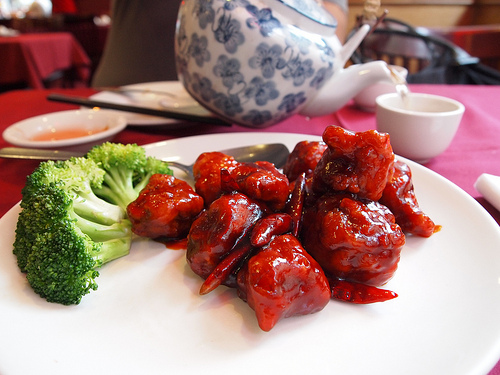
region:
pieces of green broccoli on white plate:
[6, 136, 183, 308]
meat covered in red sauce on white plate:
[116, 119, 447, 334]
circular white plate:
[1, 125, 498, 374]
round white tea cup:
[371, 80, 466, 170]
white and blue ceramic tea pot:
[170, 0, 415, 130]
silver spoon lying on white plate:
[0, 140, 292, 195]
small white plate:
[78, 69, 243, 140]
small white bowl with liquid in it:
[0, 105, 130, 162]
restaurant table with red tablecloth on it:
[0, 26, 95, 96]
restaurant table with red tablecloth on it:
[0, 76, 499, 374]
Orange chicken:
[131, 122, 443, 328]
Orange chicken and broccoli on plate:
[15, 125, 434, 325]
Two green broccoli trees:
[11, 135, 177, 297]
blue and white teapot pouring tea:
[170, 0, 400, 128]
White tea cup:
[372, 82, 470, 165]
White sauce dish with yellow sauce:
[3, 105, 127, 147]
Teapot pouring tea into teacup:
[169, 0, 470, 162]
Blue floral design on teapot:
[250, 40, 287, 79]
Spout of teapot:
[341, 59, 411, 94]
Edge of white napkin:
[474, 168, 498, 198]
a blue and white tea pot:
[174, 0, 394, 130]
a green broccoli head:
[16, 159, 130, 305]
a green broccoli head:
[79, 142, 171, 209]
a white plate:
[0, 131, 499, 372]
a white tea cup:
[374, 88, 462, 163]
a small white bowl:
[4, 107, 123, 148]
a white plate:
[87, 81, 211, 126]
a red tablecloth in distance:
[2, 33, 88, 93]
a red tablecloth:
[2, 86, 499, 224]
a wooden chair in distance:
[349, 9, 474, 81]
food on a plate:
[5, 114, 490, 373]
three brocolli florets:
[4, 133, 165, 293]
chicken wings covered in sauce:
[125, 111, 432, 347]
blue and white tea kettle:
[176, 1, 423, 133]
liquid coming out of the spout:
[379, 62, 419, 102]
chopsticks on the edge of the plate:
[37, 87, 234, 152]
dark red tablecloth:
[3, 28, 97, 86]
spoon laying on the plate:
[7, 135, 299, 192]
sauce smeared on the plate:
[158, 239, 185, 251]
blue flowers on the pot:
[172, 4, 333, 123]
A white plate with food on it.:
[45, 121, 490, 363]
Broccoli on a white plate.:
[32, 160, 147, 272]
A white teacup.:
[375, 80, 460, 165]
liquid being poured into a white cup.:
[375, 60, 425, 115]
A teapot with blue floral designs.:
[185, 40, 386, 120]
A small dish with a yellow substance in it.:
[10, 102, 116, 139]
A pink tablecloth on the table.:
[410, 65, 496, 167]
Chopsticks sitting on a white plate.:
[45, 80, 205, 130]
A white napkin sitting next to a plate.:
[455, 160, 496, 215]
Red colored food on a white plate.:
[145, 156, 381, 319]